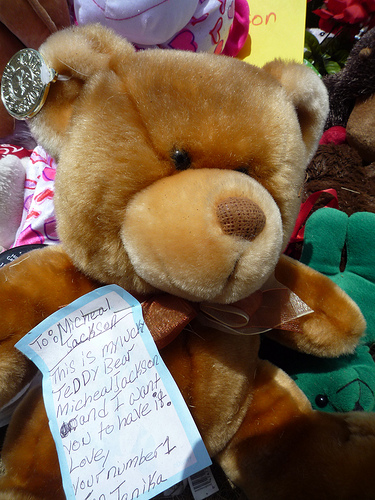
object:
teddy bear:
[0, 26, 375, 498]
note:
[15, 284, 214, 500]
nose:
[216, 196, 269, 239]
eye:
[169, 148, 192, 169]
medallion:
[0, 47, 50, 120]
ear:
[22, 23, 133, 153]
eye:
[234, 164, 254, 176]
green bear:
[284, 206, 374, 414]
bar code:
[188, 469, 219, 499]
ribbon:
[194, 292, 314, 336]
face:
[289, 353, 375, 414]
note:
[235, 1, 305, 68]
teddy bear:
[0, 1, 250, 265]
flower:
[312, 2, 374, 33]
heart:
[167, 31, 197, 53]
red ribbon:
[293, 186, 340, 242]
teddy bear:
[284, 28, 374, 275]